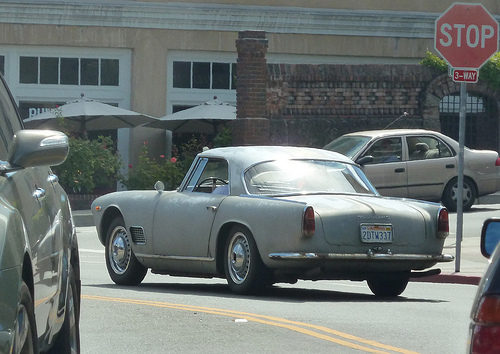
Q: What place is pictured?
A: It is a road.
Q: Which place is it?
A: It is a road.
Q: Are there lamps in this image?
A: No, there are no lamps.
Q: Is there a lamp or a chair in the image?
A: No, there are no lamps or chairs.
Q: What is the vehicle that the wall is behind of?
A: The vehicle is a car.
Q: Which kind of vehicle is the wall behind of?
A: The wall is behind the car.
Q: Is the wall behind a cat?
A: No, the wall is behind the car.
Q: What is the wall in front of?
A: The wall is in front of the building.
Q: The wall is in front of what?
A: The wall is in front of the building.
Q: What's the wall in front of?
A: The wall is in front of the building.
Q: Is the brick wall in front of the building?
A: Yes, the wall is in front of the building.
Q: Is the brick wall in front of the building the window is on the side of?
A: Yes, the wall is in front of the building.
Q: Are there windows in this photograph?
A: Yes, there is a window.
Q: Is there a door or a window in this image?
A: Yes, there is a window.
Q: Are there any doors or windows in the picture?
A: Yes, there is a window.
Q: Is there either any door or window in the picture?
A: Yes, there is a window.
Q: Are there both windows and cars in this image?
A: Yes, there are both a window and a car.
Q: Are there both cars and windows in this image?
A: Yes, there are both a window and a car.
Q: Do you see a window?
A: Yes, there is a window.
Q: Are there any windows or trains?
A: Yes, there is a window.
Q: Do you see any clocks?
A: No, there are no clocks.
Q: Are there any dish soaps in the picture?
A: No, there are no dish soaps.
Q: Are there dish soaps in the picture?
A: No, there are no dish soaps.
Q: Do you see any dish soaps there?
A: No, there are no dish soaps.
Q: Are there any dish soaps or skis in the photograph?
A: No, there are no dish soaps or skis.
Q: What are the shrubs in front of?
A: The shrubs are in front of the building.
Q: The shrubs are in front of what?
A: The shrubs are in front of the building.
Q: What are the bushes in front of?
A: The shrubs are in front of the building.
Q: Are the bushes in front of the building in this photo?
A: Yes, the bushes are in front of the building.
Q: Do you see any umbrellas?
A: Yes, there is an umbrella.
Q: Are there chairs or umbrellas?
A: Yes, there is an umbrella.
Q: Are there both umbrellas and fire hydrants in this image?
A: No, there is an umbrella but no fire hydrants.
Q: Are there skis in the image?
A: No, there are no skis.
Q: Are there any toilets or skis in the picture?
A: No, there are no skis or toilets.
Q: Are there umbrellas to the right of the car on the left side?
A: Yes, there is an umbrella to the right of the car.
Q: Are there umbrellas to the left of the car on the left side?
A: No, the umbrella is to the right of the car.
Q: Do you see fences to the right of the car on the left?
A: No, there is an umbrella to the right of the car.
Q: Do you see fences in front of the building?
A: No, there is an umbrella in front of the building.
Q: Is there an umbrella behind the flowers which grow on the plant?
A: Yes, there is an umbrella behind the flowers.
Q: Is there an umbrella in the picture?
A: Yes, there is an umbrella.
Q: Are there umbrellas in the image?
A: Yes, there is an umbrella.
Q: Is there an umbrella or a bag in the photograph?
A: Yes, there is an umbrella.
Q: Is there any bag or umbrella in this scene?
A: Yes, there is an umbrella.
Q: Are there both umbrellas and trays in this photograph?
A: No, there is an umbrella but no trays.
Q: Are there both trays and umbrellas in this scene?
A: No, there is an umbrella but no trays.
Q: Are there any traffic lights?
A: No, there are no traffic lights.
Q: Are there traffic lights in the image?
A: No, there are no traffic lights.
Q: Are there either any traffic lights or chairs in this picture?
A: No, there are no traffic lights or chairs.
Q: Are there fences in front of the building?
A: No, there is an umbrella in front of the building.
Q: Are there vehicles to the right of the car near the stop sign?
A: Yes, there is a vehicle to the right of the car.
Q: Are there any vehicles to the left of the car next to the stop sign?
A: No, the vehicle is to the right of the car.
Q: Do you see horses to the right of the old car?
A: No, there is a vehicle to the right of the car.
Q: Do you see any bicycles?
A: No, there are no bicycles.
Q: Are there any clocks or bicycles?
A: No, there are no bicycles or clocks.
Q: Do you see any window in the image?
A: Yes, there are windows.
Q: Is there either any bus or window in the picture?
A: Yes, there are windows.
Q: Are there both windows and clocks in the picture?
A: No, there are windows but no clocks.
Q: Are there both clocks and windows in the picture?
A: No, there are windows but no clocks.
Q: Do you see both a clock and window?
A: No, there are windows but no clocks.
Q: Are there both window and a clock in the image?
A: No, there are windows but no clocks.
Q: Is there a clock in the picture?
A: No, there are no clocks.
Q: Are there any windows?
A: Yes, there is a window.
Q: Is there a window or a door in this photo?
A: Yes, there is a window.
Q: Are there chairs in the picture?
A: No, there are no chairs.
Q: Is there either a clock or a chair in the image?
A: No, there are no chairs or clocks.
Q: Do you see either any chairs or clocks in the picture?
A: No, there are no chairs or clocks.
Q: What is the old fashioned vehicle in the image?
A: The vehicle is a car.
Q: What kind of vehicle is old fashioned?
A: The vehicle is a car.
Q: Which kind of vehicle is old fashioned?
A: The vehicle is a car.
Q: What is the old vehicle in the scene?
A: The vehicle is a car.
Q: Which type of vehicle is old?
A: The vehicle is a car.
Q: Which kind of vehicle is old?
A: The vehicle is a car.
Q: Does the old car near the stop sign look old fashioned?
A: Yes, the car is old fashioned.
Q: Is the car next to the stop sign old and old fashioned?
A: Yes, the car is old and old fashioned.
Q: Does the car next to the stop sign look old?
A: Yes, the car is old.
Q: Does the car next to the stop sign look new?
A: No, the car is old.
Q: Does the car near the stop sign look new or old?
A: The car is old.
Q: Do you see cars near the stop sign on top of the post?
A: Yes, there is a car near the stop sign.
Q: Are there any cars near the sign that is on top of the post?
A: Yes, there is a car near the stop sign.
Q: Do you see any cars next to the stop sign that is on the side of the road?
A: Yes, there is a car next to the stop sign.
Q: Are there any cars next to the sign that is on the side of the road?
A: Yes, there is a car next to the stop sign.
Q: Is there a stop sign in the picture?
A: Yes, there is a stop sign.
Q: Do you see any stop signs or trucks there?
A: Yes, there is a stop sign.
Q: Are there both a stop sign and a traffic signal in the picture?
A: No, there is a stop sign but no traffic lights.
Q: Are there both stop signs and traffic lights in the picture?
A: No, there is a stop sign but no traffic lights.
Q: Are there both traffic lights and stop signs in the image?
A: No, there is a stop sign but no traffic lights.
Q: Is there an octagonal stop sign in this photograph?
A: Yes, there is an octagonal stop sign.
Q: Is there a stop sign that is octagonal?
A: Yes, there is a stop sign that is octagonal.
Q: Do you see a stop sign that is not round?
A: Yes, there is a octagonal stop sign.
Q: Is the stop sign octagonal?
A: Yes, the stop sign is octagonal.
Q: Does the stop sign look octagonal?
A: Yes, the stop sign is octagonal.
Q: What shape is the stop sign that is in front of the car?
A: The stop sign is octagonal.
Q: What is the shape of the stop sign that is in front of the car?
A: The stop sign is octagonal.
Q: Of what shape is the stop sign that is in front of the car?
A: The stop sign is octagonal.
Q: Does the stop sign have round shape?
A: No, the stop sign is octagonal.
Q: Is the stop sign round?
A: No, the stop sign is octagonal.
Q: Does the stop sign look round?
A: No, the stop sign is octagonal.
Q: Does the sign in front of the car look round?
A: No, the stop sign is octagonal.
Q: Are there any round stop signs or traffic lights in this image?
A: No, there is a stop sign but it is octagonal.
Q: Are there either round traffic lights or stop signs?
A: No, there is a stop sign but it is octagonal.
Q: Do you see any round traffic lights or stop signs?
A: No, there is a stop sign but it is octagonal.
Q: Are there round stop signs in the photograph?
A: No, there is a stop sign but it is octagonal.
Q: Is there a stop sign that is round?
A: No, there is a stop sign but it is octagonal.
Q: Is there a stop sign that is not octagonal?
A: No, there is a stop sign but it is octagonal.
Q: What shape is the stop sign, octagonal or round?
A: The stop sign is octagonal.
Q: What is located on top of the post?
A: The stop sign is on top of the post.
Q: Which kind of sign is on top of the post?
A: The sign is a stop sign.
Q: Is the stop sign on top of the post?
A: Yes, the stop sign is on top of the post.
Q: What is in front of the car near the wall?
A: The stop sign is in front of the car.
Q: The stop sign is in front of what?
A: The stop sign is in front of the car.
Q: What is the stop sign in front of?
A: The stop sign is in front of the car.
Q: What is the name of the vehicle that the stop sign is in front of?
A: The vehicle is a car.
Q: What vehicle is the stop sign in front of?
A: The stop sign is in front of the car.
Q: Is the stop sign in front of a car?
A: Yes, the stop sign is in front of a car.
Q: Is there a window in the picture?
A: Yes, there is a window.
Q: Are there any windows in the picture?
A: Yes, there is a window.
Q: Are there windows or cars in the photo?
A: Yes, there is a window.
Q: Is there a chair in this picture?
A: No, there are no chairs.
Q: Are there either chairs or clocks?
A: No, there are no chairs or clocks.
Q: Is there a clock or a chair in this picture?
A: No, there are no chairs or clocks.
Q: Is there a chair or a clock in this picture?
A: No, there are no chairs or clocks.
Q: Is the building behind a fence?
A: No, the building is behind the umbrella.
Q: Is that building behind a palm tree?
A: No, the building is behind an umbrella.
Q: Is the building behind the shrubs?
A: Yes, the building is behind the shrubs.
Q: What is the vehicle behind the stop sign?
A: The vehicle is a car.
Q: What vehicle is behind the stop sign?
A: The vehicle is a car.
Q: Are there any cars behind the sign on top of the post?
A: Yes, there is a car behind the stop sign.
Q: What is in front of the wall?
A: The car is in front of the wall.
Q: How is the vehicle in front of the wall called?
A: The vehicle is a car.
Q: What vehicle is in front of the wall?
A: The vehicle is a car.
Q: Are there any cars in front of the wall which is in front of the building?
A: Yes, there is a car in front of the wall.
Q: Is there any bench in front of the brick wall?
A: No, there is a car in front of the wall.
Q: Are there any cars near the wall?
A: Yes, there is a car near the wall.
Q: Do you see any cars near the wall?
A: Yes, there is a car near the wall.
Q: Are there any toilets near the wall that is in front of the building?
A: No, there is a car near the wall.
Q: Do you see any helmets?
A: No, there are no helmets.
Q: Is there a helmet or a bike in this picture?
A: No, there are no helmets or bikes.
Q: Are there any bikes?
A: No, there are no bikes.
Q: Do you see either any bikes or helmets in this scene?
A: No, there are no bikes or helmets.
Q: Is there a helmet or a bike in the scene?
A: No, there are no bikes or helmets.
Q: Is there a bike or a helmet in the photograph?
A: No, there are no bikes or helmets.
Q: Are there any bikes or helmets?
A: No, there are no bikes or helmets.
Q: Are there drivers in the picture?
A: No, there are no drivers.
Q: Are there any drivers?
A: No, there are no drivers.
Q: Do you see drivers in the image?
A: No, there are no drivers.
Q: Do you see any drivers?
A: No, there are no drivers.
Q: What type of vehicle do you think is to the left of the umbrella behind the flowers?
A: The vehicle is a car.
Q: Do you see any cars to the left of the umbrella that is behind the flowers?
A: Yes, there is a car to the left of the umbrella.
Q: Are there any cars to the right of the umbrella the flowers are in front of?
A: No, the car is to the left of the umbrella.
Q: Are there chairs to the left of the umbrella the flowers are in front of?
A: No, there is a car to the left of the umbrella.